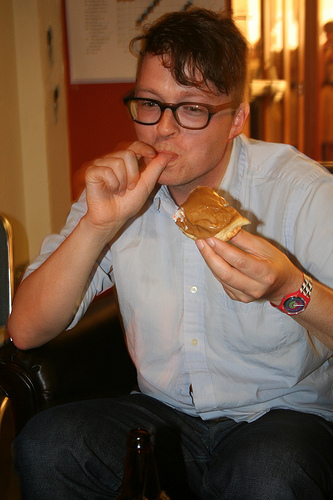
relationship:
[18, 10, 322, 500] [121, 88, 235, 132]
man has glasses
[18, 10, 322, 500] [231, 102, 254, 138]
man has ear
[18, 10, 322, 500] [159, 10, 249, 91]
man has hair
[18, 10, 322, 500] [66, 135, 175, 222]
man has hand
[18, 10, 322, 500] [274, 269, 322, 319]
man has watch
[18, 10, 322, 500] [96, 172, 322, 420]
man wears shirt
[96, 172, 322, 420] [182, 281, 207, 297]
shirt has button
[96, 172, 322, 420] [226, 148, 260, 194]
shirt has collar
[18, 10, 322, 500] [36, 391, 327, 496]
man wears pants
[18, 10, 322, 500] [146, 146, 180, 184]
man sucks thumb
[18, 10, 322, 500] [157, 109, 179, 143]
man has nose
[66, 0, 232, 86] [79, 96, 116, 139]
board on wall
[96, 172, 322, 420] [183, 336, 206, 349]
shirt has button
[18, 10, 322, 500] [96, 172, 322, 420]
man in shirt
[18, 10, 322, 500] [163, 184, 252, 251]
man holding doughnut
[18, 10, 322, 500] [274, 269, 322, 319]
man wearing watch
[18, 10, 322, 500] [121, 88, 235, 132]
man wearing glasses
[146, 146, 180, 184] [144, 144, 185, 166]
thumb in mouth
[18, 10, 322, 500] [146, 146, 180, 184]
man licking thumb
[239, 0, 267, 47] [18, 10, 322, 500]
light behind man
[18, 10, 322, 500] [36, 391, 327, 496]
man wearing pants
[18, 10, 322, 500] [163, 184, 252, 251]
man eating sandwitch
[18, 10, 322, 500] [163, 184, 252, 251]
man eating doughnut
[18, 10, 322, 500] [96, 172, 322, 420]
man wearing shirt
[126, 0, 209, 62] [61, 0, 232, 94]
crossword on board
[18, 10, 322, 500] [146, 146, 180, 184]
man sucking thumb